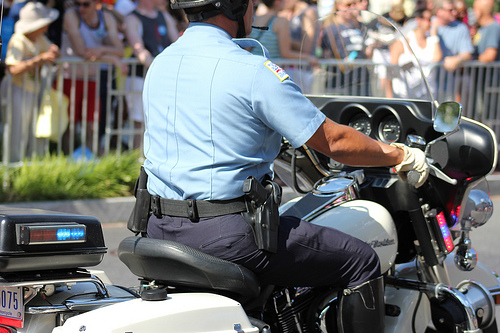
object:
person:
[61, 0, 131, 157]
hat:
[9, 0, 61, 38]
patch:
[264, 57, 292, 80]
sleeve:
[223, 38, 330, 150]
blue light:
[51, 225, 88, 244]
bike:
[0, 0, 499, 333]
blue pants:
[133, 201, 384, 294]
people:
[1, 2, 62, 162]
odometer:
[361, 105, 412, 151]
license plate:
[2, 282, 24, 319]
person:
[389, 15, 444, 99]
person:
[321, 2, 376, 94]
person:
[464, 0, 498, 62]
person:
[435, 3, 473, 109]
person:
[123, 2, 196, 122]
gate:
[6, 52, 498, 167]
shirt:
[143, 23, 330, 205]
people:
[428, 0, 475, 72]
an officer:
[130, 0, 431, 333]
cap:
[171, 0, 251, 16]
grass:
[3, 150, 145, 203]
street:
[2, 194, 499, 329]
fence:
[1, 55, 498, 169]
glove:
[388, 142, 430, 188]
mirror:
[425, 99, 467, 131]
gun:
[242, 168, 284, 255]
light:
[14, 221, 92, 250]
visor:
[298, 7, 437, 117]